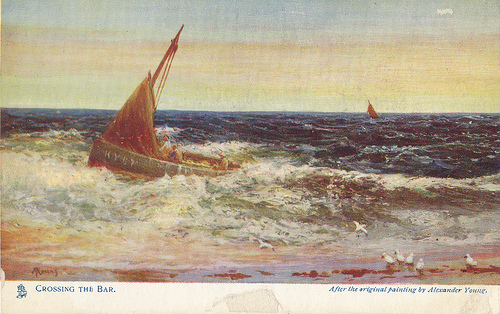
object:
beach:
[0, 239, 499, 313]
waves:
[0, 123, 497, 245]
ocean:
[0, 106, 499, 280]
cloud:
[0, 33, 495, 102]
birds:
[256, 241, 280, 249]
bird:
[351, 217, 370, 237]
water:
[96, 186, 317, 269]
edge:
[168, 154, 214, 178]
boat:
[87, 24, 249, 190]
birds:
[381, 250, 404, 271]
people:
[158, 131, 185, 165]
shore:
[14, 231, 484, 288]